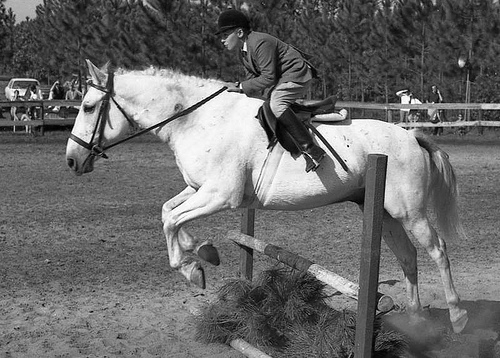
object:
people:
[425, 85, 443, 136]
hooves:
[190, 244, 221, 289]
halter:
[69, 70, 134, 159]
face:
[65, 86, 127, 176]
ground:
[363, 110, 409, 139]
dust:
[351, 270, 499, 357]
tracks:
[16, 215, 178, 355]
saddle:
[255, 94, 348, 172]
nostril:
[67, 157, 77, 168]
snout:
[66, 152, 85, 176]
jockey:
[213, 9, 327, 173]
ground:
[392, 99, 413, 134]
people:
[28, 84, 45, 133]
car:
[4, 77, 45, 101]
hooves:
[412, 312, 469, 333]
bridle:
[103, 85, 228, 151]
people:
[395, 89, 422, 130]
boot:
[277, 107, 326, 173]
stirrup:
[301, 149, 322, 172]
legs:
[161, 185, 245, 269]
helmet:
[214, 9, 251, 36]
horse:
[65, 58, 469, 334]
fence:
[213, 153, 394, 358]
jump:
[65, 58, 469, 333]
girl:
[214, 10, 327, 173]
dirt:
[32, 267, 151, 355]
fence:
[0, 99, 500, 136]